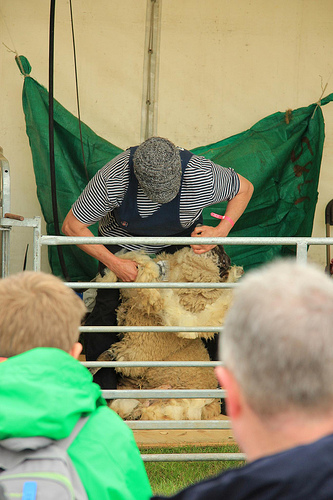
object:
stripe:
[197, 177, 214, 182]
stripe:
[184, 205, 196, 219]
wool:
[137, 289, 184, 346]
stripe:
[103, 166, 126, 181]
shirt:
[70, 147, 240, 256]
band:
[210, 212, 234, 228]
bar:
[34, 234, 333, 461]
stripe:
[101, 222, 119, 232]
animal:
[105, 245, 243, 421]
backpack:
[0, 412, 89, 500]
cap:
[133, 137, 182, 204]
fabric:
[14, 54, 333, 283]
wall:
[0, 0, 333, 318]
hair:
[218, 257, 332, 421]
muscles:
[68, 218, 83, 234]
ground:
[147, 446, 239, 498]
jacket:
[1, 347, 156, 500]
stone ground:
[133, 424, 223, 447]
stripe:
[94, 180, 101, 188]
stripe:
[119, 156, 127, 171]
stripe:
[84, 204, 93, 222]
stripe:
[95, 196, 102, 208]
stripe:
[109, 197, 123, 202]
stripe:
[219, 170, 227, 189]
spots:
[218, 28, 262, 55]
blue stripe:
[139, 203, 155, 212]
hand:
[190, 225, 215, 254]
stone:
[221, 442, 231, 450]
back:
[0, 399, 132, 499]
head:
[132, 135, 181, 205]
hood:
[0, 346, 107, 442]